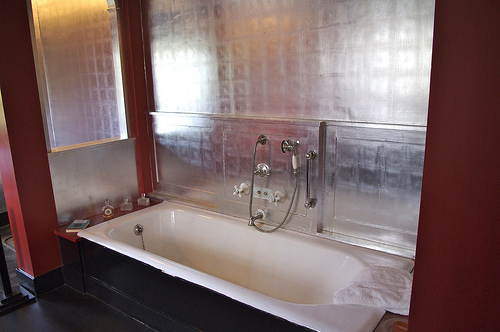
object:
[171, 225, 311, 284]
empty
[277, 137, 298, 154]
head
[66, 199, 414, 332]
bathtub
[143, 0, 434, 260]
glass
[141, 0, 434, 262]
frosted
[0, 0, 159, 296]
walls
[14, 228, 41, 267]
red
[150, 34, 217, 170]
light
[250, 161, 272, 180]
knobs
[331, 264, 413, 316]
towel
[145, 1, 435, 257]
wall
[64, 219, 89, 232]
book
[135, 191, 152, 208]
bottles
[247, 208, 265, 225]
faucet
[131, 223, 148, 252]
drain